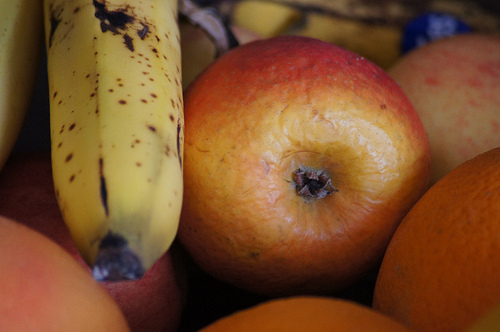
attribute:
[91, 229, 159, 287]
end — triangular 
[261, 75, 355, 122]
skin — wrinkly 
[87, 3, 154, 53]
spot — brown, black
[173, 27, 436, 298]
apple — red, yellow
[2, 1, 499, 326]
fruit — blurry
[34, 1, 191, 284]
banana — overripe, yellow